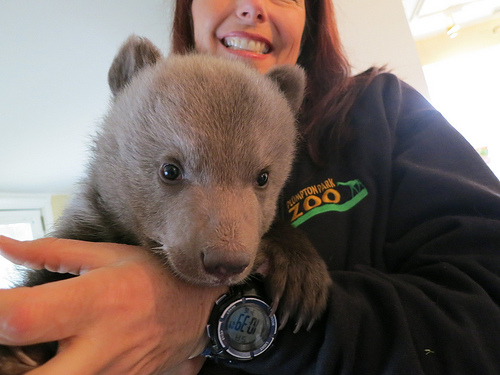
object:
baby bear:
[12, 33, 334, 336]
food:
[4, 228, 65, 367]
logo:
[286, 178, 369, 228]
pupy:
[137, 127, 277, 288]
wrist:
[195, 246, 299, 373]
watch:
[196, 273, 282, 375]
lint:
[424, 349, 434, 355]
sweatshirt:
[199, 67, 500, 375]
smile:
[213, 20, 284, 60]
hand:
[0, 235, 230, 375]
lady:
[1, 0, 500, 375]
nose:
[203, 246, 250, 277]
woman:
[1, 0, 500, 375]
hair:
[173, 0, 191, 46]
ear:
[265, 63, 306, 113]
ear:
[108, 34, 163, 96]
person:
[0, 0, 500, 375]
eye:
[163, 166, 180, 181]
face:
[126, 108, 297, 287]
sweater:
[197, 66, 499, 375]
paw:
[268, 242, 332, 334]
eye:
[257, 173, 268, 186]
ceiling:
[28, 27, 91, 98]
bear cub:
[20, 33, 333, 336]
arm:
[270, 66, 499, 375]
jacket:
[199, 72, 500, 375]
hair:
[313, 61, 342, 105]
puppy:
[14, 31, 330, 334]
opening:
[420, 14, 486, 94]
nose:
[236, 1, 265, 22]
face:
[188, 0, 306, 74]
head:
[171, 0, 394, 168]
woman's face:
[191, 0, 306, 75]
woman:
[159, 9, 399, 369]